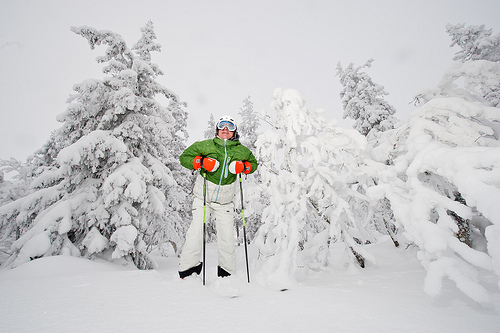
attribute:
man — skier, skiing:
[181, 116, 260, 285]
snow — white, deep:
[5, 256, 498, 332]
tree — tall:
[30, 23, 196, 271]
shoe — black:
[181, 262, 206, 279]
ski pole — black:
[233, 165, 255, 288]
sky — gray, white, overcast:
[1, 1, 499, 159]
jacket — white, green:
[181, 141, 258, 207]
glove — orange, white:
[228, 160, 253, 176]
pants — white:
[177, 198, 240, 280]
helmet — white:
[216, 111, 239, 125]